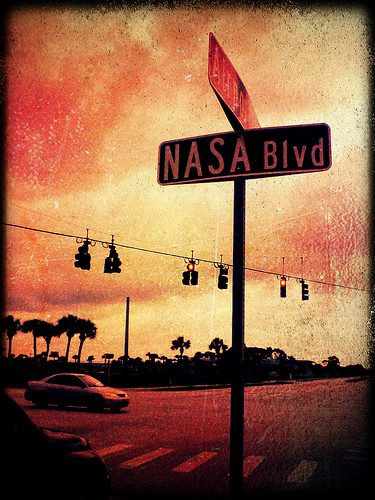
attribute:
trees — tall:
[3, 307, 98, 367]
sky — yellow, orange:
[23, 143, 171, 230]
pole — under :
[226, 174, 245, 498]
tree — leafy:
[74, 316, 97, 365]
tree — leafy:
[53, 313, 81, 361]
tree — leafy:
[35, 316, 53, 362]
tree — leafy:
[17, 318, 41, 358]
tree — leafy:
[0, 313, 23, 355]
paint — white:
[83, 429, 335, 499]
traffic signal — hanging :
[139, 217, 235, 288]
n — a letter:
[164, 143, 179, 179]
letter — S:
[204, 133, 224, 174]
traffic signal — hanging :
[182, 259, 197, 285]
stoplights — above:
[63, 228, 321, 312]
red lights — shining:
[181, 258, 313, 303]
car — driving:
[16, 346, 116, 397]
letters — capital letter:
[160, 144, 180, 180]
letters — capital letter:
[183, 138, 202, 176]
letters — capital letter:
[205, 136, 223, 174]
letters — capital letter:
[228, 135, 252, 173]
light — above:
[278, 276, 287, 296]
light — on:
[186, 262, 195, 270]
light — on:
[278, 278, 287, 286]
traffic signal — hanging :
[70, 229, 97, 269]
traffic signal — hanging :
[267, 255, 289, 306]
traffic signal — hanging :
[291, 271, 361, 292]